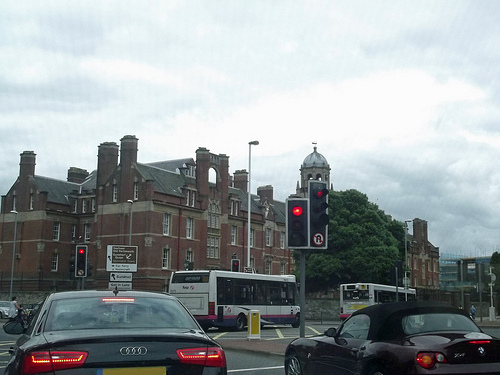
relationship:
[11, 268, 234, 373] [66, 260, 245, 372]
symbol on car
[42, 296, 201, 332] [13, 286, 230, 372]
window on car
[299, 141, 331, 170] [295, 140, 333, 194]
building top of tower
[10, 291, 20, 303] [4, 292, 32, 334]
head of person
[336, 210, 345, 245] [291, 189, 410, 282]
leaves on tree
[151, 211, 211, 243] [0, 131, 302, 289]
two windows on a building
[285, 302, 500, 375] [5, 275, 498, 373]
car on street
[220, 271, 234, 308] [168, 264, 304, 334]
window of bus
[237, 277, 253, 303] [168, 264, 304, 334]
window of bus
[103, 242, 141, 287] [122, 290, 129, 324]
signs on pole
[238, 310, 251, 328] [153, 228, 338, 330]
tire of bus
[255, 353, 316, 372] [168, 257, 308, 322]
wheels on a bus